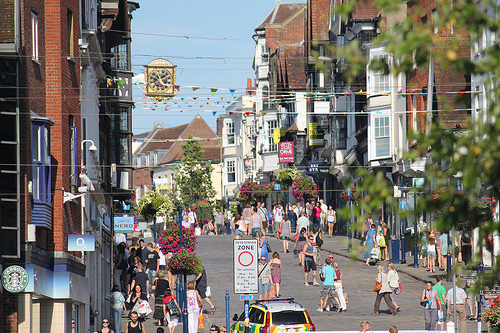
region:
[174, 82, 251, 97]
Different colored flags hanging on line.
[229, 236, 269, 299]
White sign with red circle.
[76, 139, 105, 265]
Light mounted on wall of building.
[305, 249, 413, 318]
People crossing the street.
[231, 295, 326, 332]
A multi-colored car parked on the curb.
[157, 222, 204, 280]
Pink flowers growing next to street.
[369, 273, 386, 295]
Woman with a brown purse.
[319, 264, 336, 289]
Boy wearing a blue shirt.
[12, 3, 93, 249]
A building built from red brick.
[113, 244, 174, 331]
People crowded on sidewalk.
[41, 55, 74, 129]
red brick façade of building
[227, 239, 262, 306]
gray sign with red circle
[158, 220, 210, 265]
cluster of red and green flowers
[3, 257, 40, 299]
Starbucks sign on building front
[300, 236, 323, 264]
man wearing short gray shirt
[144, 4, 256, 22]
crispy clear blue skies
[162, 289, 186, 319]
woman carrying oversized gray bag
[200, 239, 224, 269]
portion of gray asphalt street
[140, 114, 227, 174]
brown triangular shaped roof on building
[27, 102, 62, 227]
blue windows on building front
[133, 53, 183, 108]
Gold and black street clock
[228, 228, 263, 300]
White with black trim parking sign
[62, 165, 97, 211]
white surveillance camera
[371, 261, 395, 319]
Lady with brown purse crossing the street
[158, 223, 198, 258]
Pink hanging flowers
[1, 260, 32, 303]
Green and white starbucks coffee sign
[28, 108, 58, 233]
Blue 2nd story bay window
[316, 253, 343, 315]
boy in blue shirt crossing street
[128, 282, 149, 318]
Lady carrying shopping bags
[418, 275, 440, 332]
Lady with black purse walking down the street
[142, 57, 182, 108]
large gold clock with black borders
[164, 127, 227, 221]
tree located on busy street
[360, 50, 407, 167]
white house front with blue windows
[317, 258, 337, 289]
man wearing light green tee shirt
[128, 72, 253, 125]
mulit colored banners stretched across the street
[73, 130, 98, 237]
white curved street light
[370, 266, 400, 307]
woman carrying brown purse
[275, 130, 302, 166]
red banner on building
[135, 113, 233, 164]
brown roof tops of buildings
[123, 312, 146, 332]
man wearing black sleeveless shirt